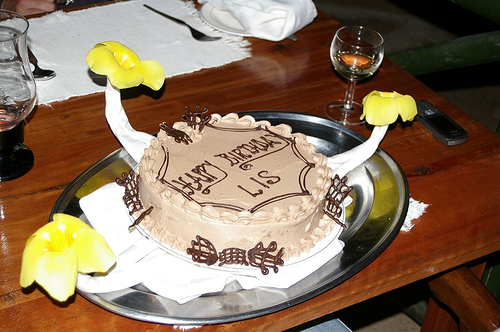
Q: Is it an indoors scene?
A: Yes, it is indoors.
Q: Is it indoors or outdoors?
A: It is indoors.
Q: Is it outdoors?
A: No, it is indoors.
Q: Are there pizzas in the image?
A: No, there are no pizzas.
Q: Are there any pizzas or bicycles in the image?
A: No, there are no pizzas or bicycles.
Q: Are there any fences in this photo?
A: No, there are no fences.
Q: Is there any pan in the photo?
A: Yes, there is a pan.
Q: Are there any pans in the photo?
A: Yes, there is a pan.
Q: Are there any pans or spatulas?
A: Yes, there is a pan.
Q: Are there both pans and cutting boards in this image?
A: No, there is a pan but no cutting boards.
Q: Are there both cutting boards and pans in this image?
A: No, there is a pan but no cutting boards.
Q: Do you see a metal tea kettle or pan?
A: Yes, there is a metal pan.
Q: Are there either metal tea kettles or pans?
A: Yes, there is a metal pan.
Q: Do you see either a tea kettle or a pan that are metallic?
A: Yes, the pan is metallic.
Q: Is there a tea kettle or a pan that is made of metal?
A: Yes, the pan is made of metal.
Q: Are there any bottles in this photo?
A: No, there are no bottles.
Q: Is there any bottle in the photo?
A: No, there are no bottles.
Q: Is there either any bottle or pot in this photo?
A: No, there are no bottles or pots.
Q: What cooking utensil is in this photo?
A: The cooking utensil is a pan.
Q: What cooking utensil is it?
A: The cooking utensil is a pan.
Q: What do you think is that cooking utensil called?
A: This is a pan.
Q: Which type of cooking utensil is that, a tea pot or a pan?
A: This is a pan.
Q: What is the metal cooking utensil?
A: The cooking utensil is a pan.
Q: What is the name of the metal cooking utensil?
A: The cooking utensil is a pan.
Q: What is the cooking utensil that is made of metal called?
A: The cooking utensil is a pan.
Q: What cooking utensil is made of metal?
A: The cooking utensil is a pan.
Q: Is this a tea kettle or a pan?
A: This is a pan.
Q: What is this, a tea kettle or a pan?
A: This is a pan.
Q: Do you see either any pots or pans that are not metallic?
A: No, there is a pan but it is metallic.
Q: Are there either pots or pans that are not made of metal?
A: No, there is a pan but it is made of metal.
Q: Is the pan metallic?
A: Yes, the pan is metallic.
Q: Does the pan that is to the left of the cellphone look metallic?
A: Yes, the pan is metallic.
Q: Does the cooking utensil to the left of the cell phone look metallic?
A: Yes, the pan is metallic.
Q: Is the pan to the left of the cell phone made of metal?
A: Yes, the pan is made of metal.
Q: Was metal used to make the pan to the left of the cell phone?
A: Yes, the pan is made of metal.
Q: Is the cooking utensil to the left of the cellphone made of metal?
A: Yes, the pan is made of metal.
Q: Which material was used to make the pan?
A: The pan is made of metal.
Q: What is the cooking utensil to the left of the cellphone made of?
A: The pan is made of metal.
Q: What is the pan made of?
A: The pan is made of metal.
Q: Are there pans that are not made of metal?
A: No, there is a pan but it is made of metal.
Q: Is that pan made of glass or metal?
A: The pan is made of metal.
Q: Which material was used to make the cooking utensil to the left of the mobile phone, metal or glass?
A: The pan is made of metal.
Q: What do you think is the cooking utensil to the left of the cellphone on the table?
A: The cooking utensil is a pan.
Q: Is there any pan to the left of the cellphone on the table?
A: Yes, there is a pan to the left of the cellphone.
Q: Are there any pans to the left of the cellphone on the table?
A: Yes, there is a pan to the left of the cellphone.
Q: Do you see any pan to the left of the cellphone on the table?
A: Yes, there is a pan to the left of the cellphone.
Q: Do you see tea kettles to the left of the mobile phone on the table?
A: No, there is a pan to the left of the cellphone.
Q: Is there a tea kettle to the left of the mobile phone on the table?
A: No, there is a pan to the left of the cellphone.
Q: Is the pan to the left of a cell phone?
A: Yes, the pan is to the left of a cell phone.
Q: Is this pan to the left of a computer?
A: No, the pan is to the left of a cell phone.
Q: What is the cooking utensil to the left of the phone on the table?
A: The cooking utensil is a pan.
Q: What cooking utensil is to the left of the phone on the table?
A: The cooking utensil is a pan.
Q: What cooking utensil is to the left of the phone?
A: The cooking utensil is a pan.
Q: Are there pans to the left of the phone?
A: Yes, there is a pan to the left of the phone.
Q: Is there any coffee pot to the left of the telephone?
A: No, there is a pan to the left of the telephone.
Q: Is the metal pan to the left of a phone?
A: Yes, the pan is to the left of a phone.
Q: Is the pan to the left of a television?
A: No, the pan is to the left of a phone.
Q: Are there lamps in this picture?
A: No, there are no lamps.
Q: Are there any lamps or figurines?
A: No, there are no lamps or figurines.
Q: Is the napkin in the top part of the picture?
A: Yes, the napkin is in the top of the image.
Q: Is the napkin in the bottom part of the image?
A: No, the napkin is in the top of the image.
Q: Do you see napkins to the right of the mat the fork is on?
A: Yes, there is a napkin to the right of the mat.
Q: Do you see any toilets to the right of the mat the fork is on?
A: No, there is a napkin to the right of the mat.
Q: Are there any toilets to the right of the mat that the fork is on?
A: No, there is a napkin to the right of the mat.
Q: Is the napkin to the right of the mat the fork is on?
A: Yes, the napkin is to the right of the mat.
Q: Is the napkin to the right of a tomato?
A: No, the napkin is to the right of the mat.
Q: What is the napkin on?
A: The napkin is on the plate.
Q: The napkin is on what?
A: The napkin is on the plate.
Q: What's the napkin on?
A: The napkin is on the plate.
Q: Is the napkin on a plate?
A: Yes, the napkin is on a plate.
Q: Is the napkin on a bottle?
A: No, the napkin is on a plate.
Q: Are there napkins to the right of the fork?
A: Yes, there is a napkin to the right of the fork.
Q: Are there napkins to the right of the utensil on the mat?
A: Yes, there is a napkin to the right of the fork.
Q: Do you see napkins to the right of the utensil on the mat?
A: Yes, there is a napkin to the right of the fork.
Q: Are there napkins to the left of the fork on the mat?
A: No, the napkin is to the right of the fork.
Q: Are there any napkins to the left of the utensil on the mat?
A: No, the napkin is to the right of the fork.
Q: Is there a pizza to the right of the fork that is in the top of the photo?
A: No, there is a napkin to the right of the fork.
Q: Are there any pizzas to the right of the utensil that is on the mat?
A: No, there is a napkin to the right of the fork.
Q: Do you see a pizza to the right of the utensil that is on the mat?
A: No, there is a napkin to the right of the fork.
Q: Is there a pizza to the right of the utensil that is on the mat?
A: No, there is a napkin to the right of the fork.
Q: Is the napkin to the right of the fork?
A: Yes, the napkin is to the right of the fork.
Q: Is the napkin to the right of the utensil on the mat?
A: Yes, the napkin is to the right of the fork.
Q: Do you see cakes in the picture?
A: Yes, there is a cake.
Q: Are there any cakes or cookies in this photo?
A: Yes, there is a cake.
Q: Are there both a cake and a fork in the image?
A: Yes, there are both a cake and a fork.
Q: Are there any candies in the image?
A: No, there are no candies.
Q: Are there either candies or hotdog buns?
A: No, there are no candies or hotdog buns.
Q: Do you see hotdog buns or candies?
A: No, there are no candies or hotdog buns.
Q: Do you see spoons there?
A: Yes, there is a spoon.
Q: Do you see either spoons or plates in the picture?
A: Yes, there is a spoon.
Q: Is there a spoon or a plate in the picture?
A: Yes, there is a spoon.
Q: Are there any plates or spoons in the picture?
A: Yes, there is a spoon.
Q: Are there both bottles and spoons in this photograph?
A: No, there is a spoon but no bottles.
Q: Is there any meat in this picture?
A: No, there is no meat.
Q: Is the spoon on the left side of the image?
A: Yes, the spoon is on the left of the image.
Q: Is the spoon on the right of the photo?
A: No, the spoon is on the left of the image.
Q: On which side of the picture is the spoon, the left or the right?
A: The spoon is on the left of the image.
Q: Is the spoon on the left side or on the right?
A: The spoon is on the left of the image.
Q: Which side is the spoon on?
A: The spoon is on the left of the image.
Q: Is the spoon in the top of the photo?
A: Yes, the spoon is in the top of the image.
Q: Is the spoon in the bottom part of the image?
A: No, the spoon is in the top of the image.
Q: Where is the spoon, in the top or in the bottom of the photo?
A: The spoon is in the top of the image.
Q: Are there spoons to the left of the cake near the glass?
A: Yes, there is a spoon to the left of the cake.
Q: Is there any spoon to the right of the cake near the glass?
A: No, the spoon is to the left of the cake.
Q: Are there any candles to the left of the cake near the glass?
A: No, there is a spoon to the left of the cake.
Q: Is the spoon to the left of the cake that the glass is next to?
A: Yes, the spoon is to the left of the cake.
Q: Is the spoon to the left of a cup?
A: No, the spoon is to the left of the cake.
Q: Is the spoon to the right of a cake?
A: No, the spoon is to the left of a cake.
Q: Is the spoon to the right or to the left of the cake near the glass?
A: The spoon is to the left of the cake.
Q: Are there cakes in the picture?
A: Yes, there is a cake.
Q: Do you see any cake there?
A: Yes, there is a cake.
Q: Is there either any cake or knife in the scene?
A: Yes, there is a cake.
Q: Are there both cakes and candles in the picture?
A: No, there is a cake but no candles.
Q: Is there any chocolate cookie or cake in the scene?
A: Yes, there is a chocolate cake.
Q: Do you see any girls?
A: No, there are no girls.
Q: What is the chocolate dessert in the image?
A: The dessert is a cake.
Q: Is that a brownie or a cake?
A: That is a cake.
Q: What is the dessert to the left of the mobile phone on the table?
A: The dessert is a cake.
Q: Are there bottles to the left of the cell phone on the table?
A: No, there is a cake to the left of the cellphone.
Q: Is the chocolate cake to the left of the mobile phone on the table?
A: Yes, the cake is to the left of the mobile phone.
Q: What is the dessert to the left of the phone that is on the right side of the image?
A: The dessert is a cake.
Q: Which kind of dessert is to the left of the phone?
A: The dessert is a cake.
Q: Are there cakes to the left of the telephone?
A: Yes, there is a cake to the left of the telephone.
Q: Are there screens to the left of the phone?
A: No, there is a cake to the left of the phone.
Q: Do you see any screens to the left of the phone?
A: No, there is a cake to the left of the phone.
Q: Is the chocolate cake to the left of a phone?
A: Yes, the cake is to the left of a phone.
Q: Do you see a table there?
A: Yes, there is a table.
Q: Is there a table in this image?
A: Yes, there is a table.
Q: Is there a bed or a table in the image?
A: Yes, there is a table.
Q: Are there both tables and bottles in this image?
A: No, there is a table but no bottles.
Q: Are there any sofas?
A: No, there are no sofas.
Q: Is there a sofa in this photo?
A: No, there are no sofas.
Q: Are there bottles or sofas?
A: No, there are no sofas or bottles.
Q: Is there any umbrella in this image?
A: No, there are no umbrellas.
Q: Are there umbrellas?
A: No, there are no umbrellas.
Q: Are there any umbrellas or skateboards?
A: No, there are no umbrellas or skateboards.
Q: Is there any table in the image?
A: Yes, there is a table.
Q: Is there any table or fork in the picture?
A: Yes, there is a table.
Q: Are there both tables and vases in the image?
A: No, there is a table but no vases.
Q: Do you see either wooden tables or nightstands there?
A: Yes, there is a wood table.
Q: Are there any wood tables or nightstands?
A: Yes, there is a wood table.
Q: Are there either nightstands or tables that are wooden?
A: Yes, the table is wooden.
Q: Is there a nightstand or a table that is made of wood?
A: Yes, the table is made of wood.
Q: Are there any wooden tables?
A: Yes, there is a wood table.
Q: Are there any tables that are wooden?
A: Yes, there is a table that is wooden.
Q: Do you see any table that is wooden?
A: Yes, there is a table that is wooden.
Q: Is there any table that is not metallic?
A: Yes, there is a wooden table.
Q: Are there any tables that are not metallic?
A: Yes, there is a wooden table.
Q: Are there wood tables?
A: Yes, there is a table that is made of wood.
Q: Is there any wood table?
A: Yes, there is a table that is made of wood.